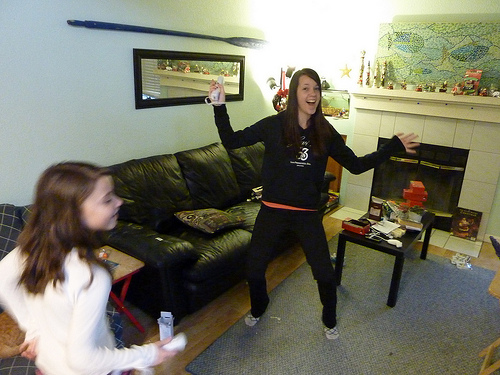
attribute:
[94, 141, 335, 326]
couch — black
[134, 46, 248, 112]
mirror — framed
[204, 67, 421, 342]
girl — smiling, playing wii, wearing black, standing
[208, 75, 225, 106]
remote — white, wii remote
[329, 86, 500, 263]
fireplace — decorated, empty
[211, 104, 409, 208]
sweatshirt — black, white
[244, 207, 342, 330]
pants — black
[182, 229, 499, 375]
rug — grey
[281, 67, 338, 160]
hair — brown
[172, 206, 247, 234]
cushion — brown, square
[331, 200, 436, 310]
coffee table — black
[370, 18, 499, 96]
picture — green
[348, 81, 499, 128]
mantle — wooden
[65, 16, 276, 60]
paddle — blue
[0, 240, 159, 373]
shirt — white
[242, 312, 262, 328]
sock — white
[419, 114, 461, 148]
tile — white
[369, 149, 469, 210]
screen — black